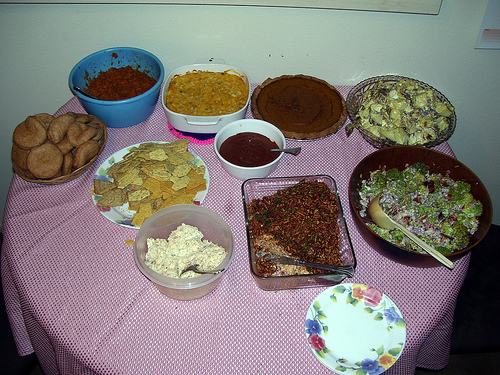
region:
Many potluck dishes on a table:
[6, 0, 493, 359]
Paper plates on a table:
[289, 282, 409, 369]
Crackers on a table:
[70, 132, 216, 219]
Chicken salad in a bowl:
[121, 198, 244, 305]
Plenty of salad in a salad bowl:
[335, 137, 496, 280]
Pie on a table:
[248, 60, 350, 145]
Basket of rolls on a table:
[3, 100, 109, 186]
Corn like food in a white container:
[156, 55, 256, 143]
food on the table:
[11, 48, 491, 303]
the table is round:
[4, 81, 468, 373]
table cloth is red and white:
[1, 83, 468, 373]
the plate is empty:
[305, 283, 405, 374]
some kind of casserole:
[242, 175, 352, 287]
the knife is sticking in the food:
[255, 250, 357, 275]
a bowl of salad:
[347, 148, 492, 268]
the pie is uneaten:
[252, 73, 344, 141]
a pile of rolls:
[11, 113, 100, 179]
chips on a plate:
[92, 139, 207, 230]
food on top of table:
[0, 56, 453, 373]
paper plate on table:
[309, 280, 401, 373]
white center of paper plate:
[333, 308, 382, 348]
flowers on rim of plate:
[343, 276, 394, 310]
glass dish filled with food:
[243, 165, 345, 295]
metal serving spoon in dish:
[271, 257, 349, 294]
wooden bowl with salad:
[348, 154, 489, 262]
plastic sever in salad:
[367, 187, 452, 272]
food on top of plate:
[91, 133, 193, 233]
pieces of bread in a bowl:
[6, 100, 103, 192]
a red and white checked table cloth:
[4, 85, 471, 373]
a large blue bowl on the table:
[66, 46, 164, 130]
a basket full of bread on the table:
[12, 112, 109, 184]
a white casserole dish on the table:
[161, 63, 251, 133]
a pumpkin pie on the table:
[250, 74, 347, 139]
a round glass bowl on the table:
[345, 77, 457, 151]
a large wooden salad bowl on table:
[350, 147, 492, 268]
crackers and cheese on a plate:
[89, 139, 210, 230]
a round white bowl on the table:
[213, 117, 288, 180]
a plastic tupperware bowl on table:
[134, 203, 235, 302]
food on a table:
[8, 23, 473, 367]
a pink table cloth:
[3, 18, 474, 374]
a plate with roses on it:
[288, 275, 419, 374]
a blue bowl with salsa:
[62, 34, 167, 134]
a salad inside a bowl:
[350, 138, 490, 269]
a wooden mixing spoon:
[358, 180, 479, 282]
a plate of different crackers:
[93, 133, 215, 245]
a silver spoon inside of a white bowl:
[206, 114, 308, 173]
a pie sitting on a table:
[246, 53, 349, 144]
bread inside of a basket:
[7, 105, 119, 206]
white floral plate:
[305, 283, 409, 374]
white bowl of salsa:
[215, 116, 285, 178]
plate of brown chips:
[90, 136, 205, 233]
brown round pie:
[249, 70, 347, 144]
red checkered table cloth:
[4, 50, 483, 366]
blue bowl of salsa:
[67, 52, 170, 131]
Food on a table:
[11, 18, 496, 372]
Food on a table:
[3, 10, 495, 373]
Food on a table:
[4, 6, 494, 373]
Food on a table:
[3, 4, 499, 371]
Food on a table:
[6, 15, 496, 373]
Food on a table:
[3, 33, 495, 374]